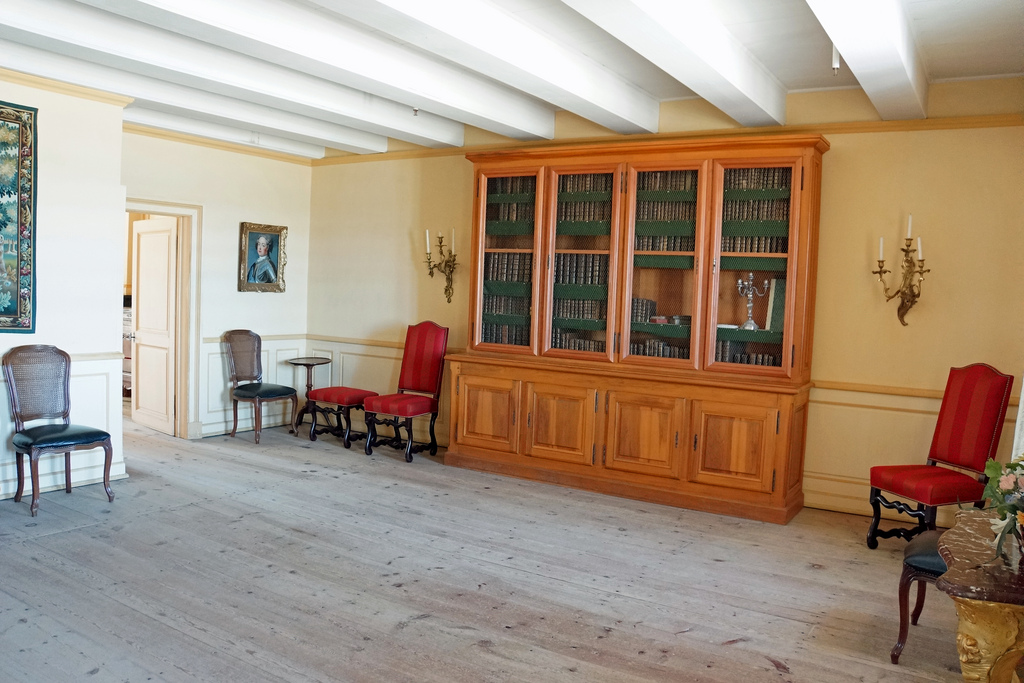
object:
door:
[455, 374, 521, 455]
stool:
[309, 319, 451, 463]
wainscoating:
[307, 117, 1024, 518]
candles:
[877, 213, 923, 262]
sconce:
[873, 237, 931, 327]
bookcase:
[443, 133, 829, 523]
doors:
[466, 157, 802, 380]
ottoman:
[307, 386, 381, 448]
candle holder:
[871, 212, 934, 327]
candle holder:
[422, 226, 463, 304]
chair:
[221, 329, 300, 442]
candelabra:
[736, 272, 769, 330]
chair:
[863, 363, 1014, 550]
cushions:
[866, 363, 1016, 507]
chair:
[3, 343, 113, 517]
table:
[288, 357, 332, 442]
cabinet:
[463, 133, 828, 379]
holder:
[736, 271, 771, 331]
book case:
[471, 163, 792, 365]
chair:
[362, 320, 450, 463]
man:
[247, 233, 277, 283]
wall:
[194, 141, 311, 438]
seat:
[11, 422, 112, 451]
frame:
[238, 222, 287, 292]